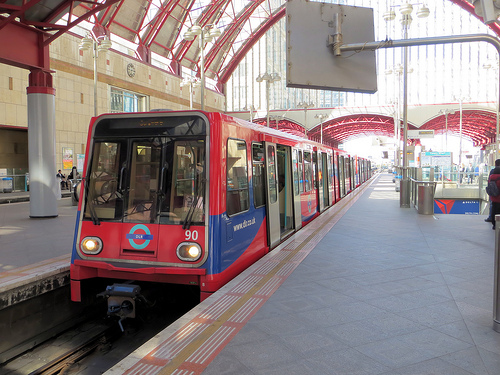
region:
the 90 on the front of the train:
[184, 230, 196, 240]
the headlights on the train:
[81, 236, 201, 259]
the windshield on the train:
[85, 119, 207, 226]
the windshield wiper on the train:
[181, 183, 208, 224]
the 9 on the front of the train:
[184, 228, 192, 241]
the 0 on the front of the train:
[191, 228, 199, 240]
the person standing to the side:
[486, 158, 499, 228]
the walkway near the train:
[143, 156, 483, 373]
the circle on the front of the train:
[123, 223, 153, 249]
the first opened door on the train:
[261, 140, 302, 241]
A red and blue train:
[65, 107, 390, 278]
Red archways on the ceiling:
[242, 113, 499, 142]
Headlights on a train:
[80, 232, 202, 261]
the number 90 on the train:
[180, 226, 202, 241]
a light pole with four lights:
[73, 26, 115, 115]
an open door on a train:
[260, 133, 304, 244]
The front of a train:
[80, 105, 225, 310]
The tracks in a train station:
[2, 313, 167, 373]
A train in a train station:
[11, 8, 499, 370]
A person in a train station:
[482, 155, 499, 223]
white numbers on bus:
[177, 227, 205, 243]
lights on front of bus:
[77, 222, 217, 299]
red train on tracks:
[86, 115, 366, 268]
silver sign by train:
[281, 21, 488, 105]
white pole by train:
[25, 68, 84, 242]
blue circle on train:
[127, 199, 152, 253]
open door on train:
[267, 141, 329, 241]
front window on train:
[91, 132, 214, 244]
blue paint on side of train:
[206, 205, 275, 262]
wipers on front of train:
[68, 185, 235, 233]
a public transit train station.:
[0, 1, 495, 371]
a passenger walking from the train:
[482, 156, 497, 221]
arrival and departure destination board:
[284, 35, 499, 92]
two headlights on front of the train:
[77, 235, 199, 262]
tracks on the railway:
[28, 330, 115, 373]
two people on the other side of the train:
[57, 165, 80, 180]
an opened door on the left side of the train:
[263, 140, 297, 250]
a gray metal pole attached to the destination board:
[345, 33, 497, 55]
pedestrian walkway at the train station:
[292, 234, 492, 374]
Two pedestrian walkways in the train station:
[0, 197, 491, 374]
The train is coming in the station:
[58, 110, 379, 325]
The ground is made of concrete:
[330, 211, 417, 368]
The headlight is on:
[74, 233, 106, 260]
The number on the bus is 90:
[183, 225, 203, 241]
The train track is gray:
[1, 309, 129, 373]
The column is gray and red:
[14, 64, 66, 221]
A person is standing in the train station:
[483, 151, 499, 227]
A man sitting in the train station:
[53, 161, 69, 190]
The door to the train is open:
[260, 140, 302, 248]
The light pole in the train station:
[78, 29, 112, 114]